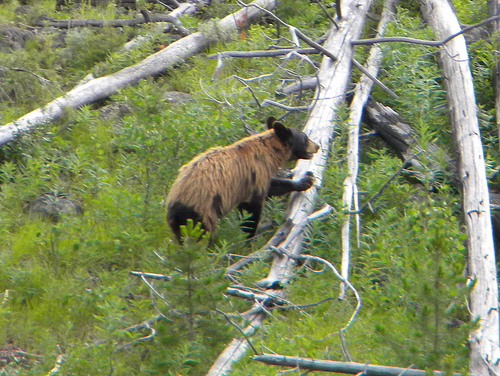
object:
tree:
[35, 8, 189, 37]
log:
[338, 0, 398, 294]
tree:
[0, 42, 70, 106]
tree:
[401, 50, 444, 138]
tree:
[71, 0, 210, 92]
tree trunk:
[204, 0, 374, 376]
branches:
[276, 246, 362, 342]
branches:
[274, 73, 317, 97]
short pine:
[151, 218, 222, 365]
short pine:
[390, 245, 464, 358]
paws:
[295, 171, 313, 191]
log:
[429, 0, 499, 66]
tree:
[205, 0, 374, 376]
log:
[202, 0, 370, 376]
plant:
[156, 337, 203, 374]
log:
[419, 0, 500, 376]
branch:
[350, 14, 499, 46]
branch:
[240, 0, 337, 60]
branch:
[203, 46, 321, 66]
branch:
[250, 352, 463, 375]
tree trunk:
[417, 0, 500, 376]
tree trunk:
[357, 88, 457, 196]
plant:
[397, 188, 451, 222]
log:
[359, 99, 454, 188]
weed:
[408, 65, 460, 363]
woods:
[307, 25, 358, 126]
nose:
[312, 143, 319, 152]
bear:
[167, 116, 320, 250]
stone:
[160, 90, 191, 104]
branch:
[256, 98, 318, 114]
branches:
[129, 269, 272, 304]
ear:
[273, 121, 290, 140]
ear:
[267, 116, 277, 129]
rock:
[24, 192, 83, 225]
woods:
[0, 0, 268, 138]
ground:
[1, 4, 492, 374]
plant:
[2, 283, 21, 322]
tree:
[0, 0, 274, 143]